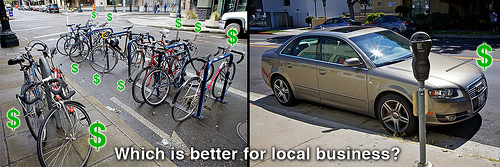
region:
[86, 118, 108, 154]
green dollar sign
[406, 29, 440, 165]
dark parking meter on metal pole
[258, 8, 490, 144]
car parked next to parking meter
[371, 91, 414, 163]
front right car wheel at curb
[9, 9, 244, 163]
several bicycles at curb and street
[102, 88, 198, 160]
white arrow painted on street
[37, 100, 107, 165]
large black bicycle wheel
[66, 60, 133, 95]
three green dollar signs with street in background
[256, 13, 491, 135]
sedan parked at curb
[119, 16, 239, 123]
many bicycles parked at racks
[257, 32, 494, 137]
silver car parked beside street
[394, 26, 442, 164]
grey metal parking meter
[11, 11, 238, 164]
row of bikes parked beside street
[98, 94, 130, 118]
trash laying on street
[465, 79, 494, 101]
company emblem on front of car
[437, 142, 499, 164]
grass growing in crack of sidewalk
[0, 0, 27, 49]
black metal street light pole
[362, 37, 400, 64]
sun reflection on windshield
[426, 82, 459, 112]
headlight on front of car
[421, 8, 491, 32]
bushes growing beside street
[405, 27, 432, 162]
silver metal parking meter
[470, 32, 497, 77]
green dollar sign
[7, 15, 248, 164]
row of parked bikes beside street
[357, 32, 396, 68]
sunlight reflecting on car windshield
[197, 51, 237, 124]
blue bike guard rail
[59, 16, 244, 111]
several bicycles locked in a bicycle rack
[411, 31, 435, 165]
a parking meter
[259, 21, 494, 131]
a car parked next to a parking meter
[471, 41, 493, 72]
a large green dollar sign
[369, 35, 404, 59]
a windshield of a car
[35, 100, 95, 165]
a wheel of a bicycle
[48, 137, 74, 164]
spokes in a bicycle wheel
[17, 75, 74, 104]
the handlebars of a bicycle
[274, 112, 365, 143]
a sidewalk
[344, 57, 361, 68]
a rear view mirror of a car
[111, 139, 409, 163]
white words which is better for local business?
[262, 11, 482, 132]
gold car parked on a street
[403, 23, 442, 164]
metal street parking meter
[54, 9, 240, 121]
bicycles parked on a street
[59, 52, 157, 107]
green dollar signs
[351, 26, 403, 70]
sun reflected on a car windshield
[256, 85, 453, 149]
shadow on the ground of a car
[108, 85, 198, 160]
white painted arrow on a street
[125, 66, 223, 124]
bicycle tires